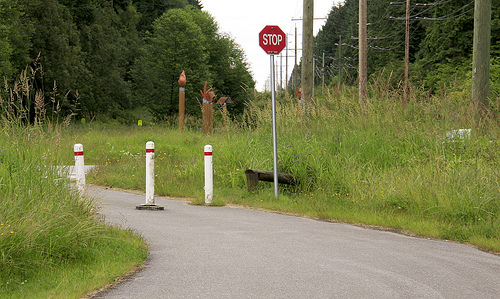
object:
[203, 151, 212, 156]
red stripe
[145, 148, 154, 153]
red stripe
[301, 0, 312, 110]
pole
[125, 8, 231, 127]
tree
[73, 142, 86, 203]
pole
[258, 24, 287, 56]
stop sign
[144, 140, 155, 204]
pole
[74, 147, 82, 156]
stripe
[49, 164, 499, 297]
road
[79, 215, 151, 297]
road edge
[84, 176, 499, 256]
road edge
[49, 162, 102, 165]
road edge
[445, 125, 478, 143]
trash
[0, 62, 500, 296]
grass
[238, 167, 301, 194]
broken post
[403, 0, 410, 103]
telephone pole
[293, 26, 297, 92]
pole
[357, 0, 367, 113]
pole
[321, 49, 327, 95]
pole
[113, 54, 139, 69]
leaves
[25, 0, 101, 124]
tree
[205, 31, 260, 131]
tree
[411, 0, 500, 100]
tree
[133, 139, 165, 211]
blockades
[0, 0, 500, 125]
forest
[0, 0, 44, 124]
trees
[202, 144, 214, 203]
pole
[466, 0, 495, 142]
pole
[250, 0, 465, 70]
electrical lines